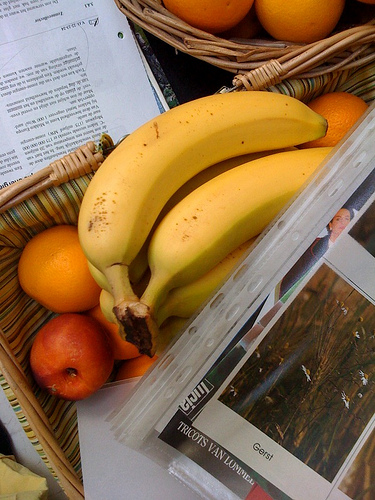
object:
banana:
[155, 236, 264, 327]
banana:
[139, 147, 335, 320]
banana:
[80, 146, 298, 296]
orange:
[299, 92, 367, 150]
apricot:
[19, 225, 102, 313]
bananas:
[99, 288, 119, 326]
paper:
[0, 1, 170, 186]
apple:
[30, 313, 114, 399]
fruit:
[18, 0, 367, 400]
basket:
[0, 26, 374, 498]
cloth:
[0, 0, 375, 499]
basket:
[118, 1, 375, 75]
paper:
[106, 99, 374, 499]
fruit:
[164, 1, 342, 42]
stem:
[112, 299, 159, 359]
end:
[319, 117, 328, 137]